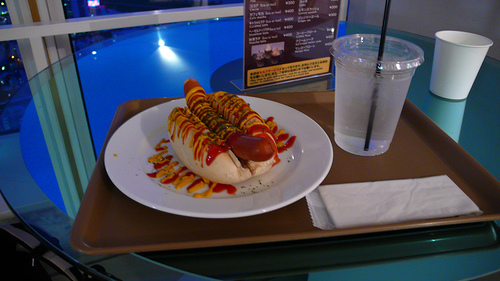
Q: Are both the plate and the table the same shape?
A: Yes, both the plate and the table are round.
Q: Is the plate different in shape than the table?
A: No, both the plate and the table are round.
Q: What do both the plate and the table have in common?
A: The shape, both the plate and the table are round.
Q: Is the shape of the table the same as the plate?
A: Yes, both the table and the plate are round.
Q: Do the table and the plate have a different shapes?
A: No, both the table and the plate are round.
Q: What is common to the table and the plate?
A: The shape, both the table and the plate are round.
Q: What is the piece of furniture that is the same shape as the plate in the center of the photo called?
A: The piece of furniture is a table.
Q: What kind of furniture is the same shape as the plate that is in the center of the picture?
A: The table is the same shape as the plate.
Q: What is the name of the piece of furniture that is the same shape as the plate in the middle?
A: The piece of furniture is a table.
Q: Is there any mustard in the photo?
A: Yes, there is mustard.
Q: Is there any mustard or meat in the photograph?
A: Yes, there is mustard.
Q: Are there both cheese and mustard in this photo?
A: No, there is mustard but no cheese.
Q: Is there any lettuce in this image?
A: No, there is no lettuce.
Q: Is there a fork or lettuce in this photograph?
A: No, there are no lettuce or forks.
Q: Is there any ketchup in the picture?
A: Yes, there is ketchup.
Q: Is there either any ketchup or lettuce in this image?
A: Yes, there is ketchup.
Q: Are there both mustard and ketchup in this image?
A: Yes, there are both ketchup and mustard.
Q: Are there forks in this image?
A: No, there are no forks.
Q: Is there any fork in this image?
A: No, there are no forks.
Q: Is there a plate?
A: Yes, there is a plate.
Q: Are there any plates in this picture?
A: Yes, there is a plate.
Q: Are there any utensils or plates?
A: Yes, there is a plate.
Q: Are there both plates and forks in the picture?
A: No, there is a plate but no forks.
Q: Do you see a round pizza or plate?
A: Yes, there is a round plate.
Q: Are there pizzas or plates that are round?
A: Yes, the plate is round.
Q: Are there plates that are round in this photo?
A: Yes, there is a round plate.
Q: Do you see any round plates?
A: Yes, there is a round plate.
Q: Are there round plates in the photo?
A: Yes, there is a round plate.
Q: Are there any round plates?
A: Yes, there is a round plate.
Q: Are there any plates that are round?
A: Yes, there is a plate that is round.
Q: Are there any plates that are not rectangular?
A: Yes, there is a round plate.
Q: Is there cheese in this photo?
A: No, there is no cheese.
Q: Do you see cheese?
A: No, there is no cheese.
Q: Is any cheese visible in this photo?
A: No, there is no cheese.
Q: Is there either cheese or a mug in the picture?
A: No, there are no cheese or mugs.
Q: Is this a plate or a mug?
A: This is a plate.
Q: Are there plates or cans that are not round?
A: No, there is a plate but it is round.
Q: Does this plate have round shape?
A: Yes, the plate is round.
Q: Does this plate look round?
A: Yes, the plate is round.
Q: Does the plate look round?
A: Yes, the plate is round.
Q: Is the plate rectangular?
A: No, the plate is round.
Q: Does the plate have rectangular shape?
A: No, the plate is round.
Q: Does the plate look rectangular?
A: No, the plate is round.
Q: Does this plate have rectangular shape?
A: No, the plate is round.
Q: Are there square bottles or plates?
A: No, there is a plate but it is round.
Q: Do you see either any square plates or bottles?
A: No, there is a plate but it is round.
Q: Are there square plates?
A: No, there is a plate but it is round.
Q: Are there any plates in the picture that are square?
A: No, there is a plate but it is round.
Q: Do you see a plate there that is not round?
A: No, there is a plate but it is round.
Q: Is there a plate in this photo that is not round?
A: No, there is a plate but it is round.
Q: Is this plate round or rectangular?
A: The plate is round.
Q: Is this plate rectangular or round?
A: The plate is round.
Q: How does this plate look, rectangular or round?
A: The plate is round.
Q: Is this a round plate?
A: Yes, this is a round plate.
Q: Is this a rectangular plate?
A: No, this is a round plate.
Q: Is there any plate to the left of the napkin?
A: Yes, there is a plate to the left of the napkin.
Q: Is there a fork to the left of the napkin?
A: No, there is a plate to the left of the napkin.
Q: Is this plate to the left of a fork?
A: No, the plate is to the left of the napkin.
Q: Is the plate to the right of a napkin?
A: No, the plate is to the left of a napkin.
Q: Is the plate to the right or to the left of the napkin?
A: The plate is to the left of the napkin.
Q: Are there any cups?
A: Yes, there is a cup.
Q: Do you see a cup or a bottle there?
A: Yes, there is a cup.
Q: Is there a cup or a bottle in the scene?
A: Yes, there is a cup.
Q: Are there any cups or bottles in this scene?
A: Yes, there is a cup.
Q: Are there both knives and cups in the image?
A: No, there is a cup but no knives.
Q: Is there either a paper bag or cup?
A: Yes, there is a paper cup.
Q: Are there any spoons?
A: No, there are no spoons.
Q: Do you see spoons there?
A: No, there are no spoons.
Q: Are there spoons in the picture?
A: No, there are no spoons.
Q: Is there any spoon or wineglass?
A: No, there are no spoons or wine glasses.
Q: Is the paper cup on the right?
A: Yes, the cup is on the right of the image.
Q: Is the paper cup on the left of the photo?
A: No, the cup is on the right of the image.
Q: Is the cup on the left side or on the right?
A: The cup is on the right of the image.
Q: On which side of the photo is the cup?
A: The cup is on the right of the image.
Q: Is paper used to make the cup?
A: Yes, the cup is made of paper.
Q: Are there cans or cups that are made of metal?
A: No, there is a cup but it is made of paper.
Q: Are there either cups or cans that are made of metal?
A: No, there is a cup but it is made of paper.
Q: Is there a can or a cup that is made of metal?
A: No, there is a cup but it is made of paper.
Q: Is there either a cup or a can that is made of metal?
A: No, there is a cup but it is made of paper.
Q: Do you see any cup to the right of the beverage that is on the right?
A: Yes, there is a cup to the right of the beverage.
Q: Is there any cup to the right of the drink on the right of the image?
A: Yes, there is a cup to the right of the beverage.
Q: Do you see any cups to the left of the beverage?
A: No, the cup is to the right of the beverage.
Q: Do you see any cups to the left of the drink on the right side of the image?
A: No, the cup is to the right of the beverage.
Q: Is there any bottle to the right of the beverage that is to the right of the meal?
A: No, there is a cup to the right of the beverage.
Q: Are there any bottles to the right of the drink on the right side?
A: No, there is a cup to the right of the beverage.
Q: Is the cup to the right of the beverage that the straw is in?
A: Yes, the cup is to the right of the beverage.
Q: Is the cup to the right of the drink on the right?
A: Yes, the cup is to the right of the beverage.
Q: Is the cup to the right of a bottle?
A: No, the cup is to the right of the beverage.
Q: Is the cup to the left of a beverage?
A: No, the cup is to the right of a beverage.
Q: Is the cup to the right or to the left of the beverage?
A: The cup is to the right of the beverage.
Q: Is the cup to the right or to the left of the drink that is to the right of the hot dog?
A: The cup is to the right of the beverage.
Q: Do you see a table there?
A: Yes, there is a table.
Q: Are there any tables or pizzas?
A: Yes, there is a table.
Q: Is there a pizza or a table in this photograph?
A: Yes, there is a table.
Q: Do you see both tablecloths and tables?
A: No, there is a table but no tablecloths.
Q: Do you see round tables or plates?
A: Yes, there is a round table.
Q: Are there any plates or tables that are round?
A: Yes, the table is round.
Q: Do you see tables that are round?
A: Yes, there is a round table.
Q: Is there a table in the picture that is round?
A: Yes, there is a table that is round.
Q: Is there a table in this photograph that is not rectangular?
A: Yes, there is a round table.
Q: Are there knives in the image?
A: No, there are no knives.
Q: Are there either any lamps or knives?
A: No, there are no knives or lamps.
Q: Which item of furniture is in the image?
A: The piece of furniture is a table.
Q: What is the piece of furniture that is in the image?
A: The piece of furniture is a table.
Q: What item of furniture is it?
A: The piece of furniture is a table.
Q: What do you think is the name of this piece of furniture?
A: This is a table.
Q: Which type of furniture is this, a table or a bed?
A: This is a table.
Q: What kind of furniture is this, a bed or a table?
A: This is a table.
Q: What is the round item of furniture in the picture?
A: The piece of furniture is a table.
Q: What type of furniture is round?
A: The furniture is a table.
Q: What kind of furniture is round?
A: The furniture is a table.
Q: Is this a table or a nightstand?
A: This is a table.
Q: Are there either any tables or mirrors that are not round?
A: No, there is a table but it is round.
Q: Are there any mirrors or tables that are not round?
A: No, there is a table but it is round.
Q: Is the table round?
A: Yes, the table is round.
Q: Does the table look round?
A: Yes, the table is round.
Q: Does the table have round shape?
A: Yes, the table is round.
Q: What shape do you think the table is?
A: The table is round.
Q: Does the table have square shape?
A: No, the table is round.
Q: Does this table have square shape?
A: No, the table is round.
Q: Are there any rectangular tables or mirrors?
A: No, there is a table but it is round.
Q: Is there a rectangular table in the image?
A: No, there is a table but it is round.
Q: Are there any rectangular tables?
A: No, there is a table but it is round.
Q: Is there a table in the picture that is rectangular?
A: No, there is a table but it is round.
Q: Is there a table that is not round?
A: No, there is a table but it is round.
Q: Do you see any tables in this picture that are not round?
A: No, there is a table but it is round.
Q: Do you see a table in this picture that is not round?
A: No, there is a table but it is round.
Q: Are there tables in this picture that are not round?
A: No, there is a table but it is round.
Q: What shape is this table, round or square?
A: The table is round.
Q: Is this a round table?
A: Yes, this is a round table.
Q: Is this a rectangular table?
A: No, this is a round table.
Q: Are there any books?
A: No, there are no books.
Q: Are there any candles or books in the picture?
A: No, there are no books or candles.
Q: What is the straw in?
A: The straw is in the beverage.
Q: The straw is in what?
A: The straw is in the beverage.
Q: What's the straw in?
A: The straw is in the beverage.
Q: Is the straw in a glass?
A: No, the straw is in the beverage.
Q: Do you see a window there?
A: Yes, there is a window.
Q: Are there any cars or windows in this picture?
A: Yes, there is a window.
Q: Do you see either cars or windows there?
A: Yes, there is a window.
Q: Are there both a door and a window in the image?
A: No, there is a window but no doors.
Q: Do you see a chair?
A: No, there are no chairs.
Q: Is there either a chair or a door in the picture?
A: No, there are no chairs or doors.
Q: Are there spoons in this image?
A: No, there are no spoons.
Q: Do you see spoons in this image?
A: No, there are no spoons.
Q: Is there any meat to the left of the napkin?
A: No, there is meal to the left of the napkin.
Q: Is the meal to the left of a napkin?
A: Yes, the meal is to the left of a napkin.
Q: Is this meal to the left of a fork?
A: No, the meal is to the left of a napkin.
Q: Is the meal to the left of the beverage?
A: Yes, the meal is to the left of the beverage.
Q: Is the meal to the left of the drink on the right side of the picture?
A: Yes, the meal is to the left of the beverage.